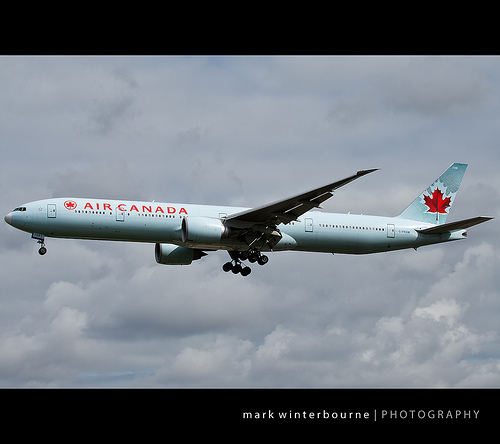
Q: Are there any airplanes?
A: Yes, there is an airplane.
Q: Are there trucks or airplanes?
A: Yes, there is an airplane.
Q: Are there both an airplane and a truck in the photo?
A: No, there is an airplane but no trucks.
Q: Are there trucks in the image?
A: No, there are no trucks.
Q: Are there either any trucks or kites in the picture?
A: No, there are no trucks or kites.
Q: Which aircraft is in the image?
A: The aircraft is an airplane.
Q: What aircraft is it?
A: The aircraft is an airplane.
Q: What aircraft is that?
A: This is an airplane.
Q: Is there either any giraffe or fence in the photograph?
A: No, there are no fences or giraffes.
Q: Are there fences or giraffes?
A: No, there are no fences or giraffes.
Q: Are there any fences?
A: No, there are no fences.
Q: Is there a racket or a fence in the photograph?
A: No, there are no fences or rackets.